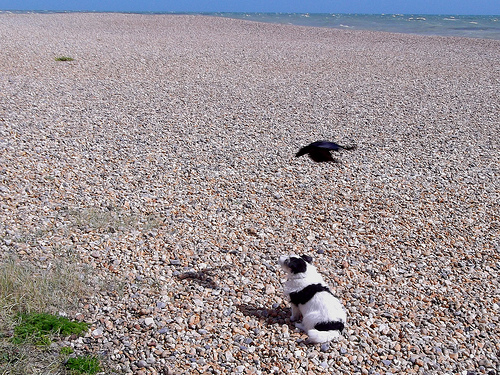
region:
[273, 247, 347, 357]
white and black dog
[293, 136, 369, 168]
blackbird flying through the air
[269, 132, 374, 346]
blackbird flying above dog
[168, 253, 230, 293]
shadow of blackbird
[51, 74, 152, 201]
part of a pebble-covered beach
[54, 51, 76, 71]
patch of weeds growing through pebbles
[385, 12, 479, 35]
ocean with waves rolling in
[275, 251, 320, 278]
white dog head with black ears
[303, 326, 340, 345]
white tail of dog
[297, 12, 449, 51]
ocean meets the shoreline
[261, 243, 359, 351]
small black and white dog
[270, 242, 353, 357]
small dog sitting on gravel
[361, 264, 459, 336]
brown and tan gravel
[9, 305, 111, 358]
patch of grass in gravel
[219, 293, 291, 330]
shadow of a dog on the ground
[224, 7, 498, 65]
water in the distance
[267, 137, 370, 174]
black bird in the air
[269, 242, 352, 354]
fluffy black and white dog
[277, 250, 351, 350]
white dog with black stripes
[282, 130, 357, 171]
black bird flapping wings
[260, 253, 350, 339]
A black and white dog sitting on gravel.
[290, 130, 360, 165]
A black bird in flight.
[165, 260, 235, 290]
A bird's shadow on the gravel.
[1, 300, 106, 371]
Green plants growing next to the gravel.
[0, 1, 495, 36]
Waves on the water.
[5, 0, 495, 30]
White capping on the water.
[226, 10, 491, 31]
The water is light blue.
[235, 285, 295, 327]
The dog's shadow on the gravel.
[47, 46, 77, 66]
A small plant surrounded by gravel.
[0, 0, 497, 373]
A black and white dog on a beach.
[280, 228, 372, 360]
a black and white dog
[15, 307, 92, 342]
a patch of green grass amid gravel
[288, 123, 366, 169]
black bird flying overhead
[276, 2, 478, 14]
a clear blue sky overhead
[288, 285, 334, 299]
a black patch on a dog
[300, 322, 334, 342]
a fluffy white tail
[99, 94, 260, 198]
pink and gray gravel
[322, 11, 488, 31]
a blue mountain in the distance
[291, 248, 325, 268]
black ears on head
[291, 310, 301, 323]
a white paw on the ground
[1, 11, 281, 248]
a rocky beach on a sunny day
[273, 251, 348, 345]
small black and white dog on the beach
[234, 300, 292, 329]
shadow of a black and white dog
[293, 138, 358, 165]
black crow flying over a rocky beach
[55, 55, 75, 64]
small patch of grass on a rocky beach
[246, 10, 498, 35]
ocean by a rocky beach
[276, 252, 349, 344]
black and white dog staring at the sky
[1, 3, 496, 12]
blue cloudless sky visible from the beach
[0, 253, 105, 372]
patches of grass by the rocky beach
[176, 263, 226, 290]
shadow of a bird flying over the beach